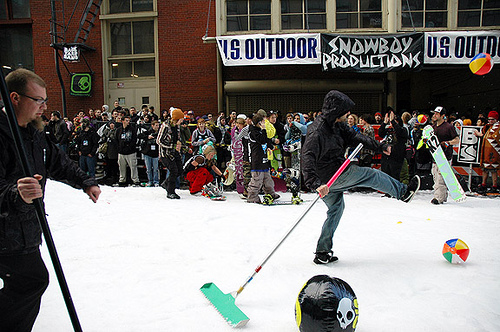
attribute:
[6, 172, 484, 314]
snow — white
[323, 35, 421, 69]
letters — white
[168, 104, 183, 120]
hat — orange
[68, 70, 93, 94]
sign — green, black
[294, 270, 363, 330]
ball — black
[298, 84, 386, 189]
jacket — black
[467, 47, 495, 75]
ball — colorful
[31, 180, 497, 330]
snow — white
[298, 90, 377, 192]
jacket — black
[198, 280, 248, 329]
shovel — teal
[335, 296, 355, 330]
skull — white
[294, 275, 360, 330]
ball — black 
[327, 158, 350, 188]
tape — pink 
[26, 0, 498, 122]
building — red, brick